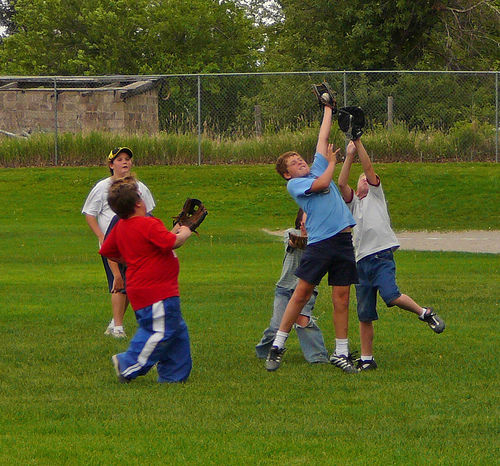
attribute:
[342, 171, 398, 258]
shirt — white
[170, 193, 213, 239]
brown glove — baseball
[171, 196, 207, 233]
baseball glove — black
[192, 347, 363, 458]
grass — short, green, brown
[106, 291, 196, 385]
pants — blue and white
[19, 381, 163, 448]
grass — brown, green, short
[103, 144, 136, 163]
hat — black, yellow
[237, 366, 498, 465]
grass — green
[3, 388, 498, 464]
grass — brown, green, short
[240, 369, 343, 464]
grass — brown, green, short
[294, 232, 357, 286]
shorts — blue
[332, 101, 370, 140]
glove — black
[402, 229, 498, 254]
gravel — light brown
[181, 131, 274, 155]
grass — long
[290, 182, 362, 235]
shirt — blue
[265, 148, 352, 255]
shirt — blue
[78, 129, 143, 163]
hat — yellow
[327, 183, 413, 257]
shirt — grey